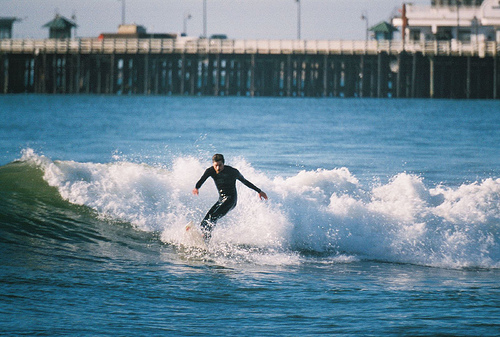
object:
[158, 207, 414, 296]
waves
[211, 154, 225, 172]
head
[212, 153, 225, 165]
hair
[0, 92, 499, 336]
water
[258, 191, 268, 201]
hand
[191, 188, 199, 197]
hand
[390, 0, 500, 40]
shelter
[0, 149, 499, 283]
surfing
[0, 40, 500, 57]
fence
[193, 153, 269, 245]
surfer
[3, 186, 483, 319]
capped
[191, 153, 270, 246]
male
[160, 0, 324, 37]
clouds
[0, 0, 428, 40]
sky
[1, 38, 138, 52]
pier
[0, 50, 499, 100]
pillar